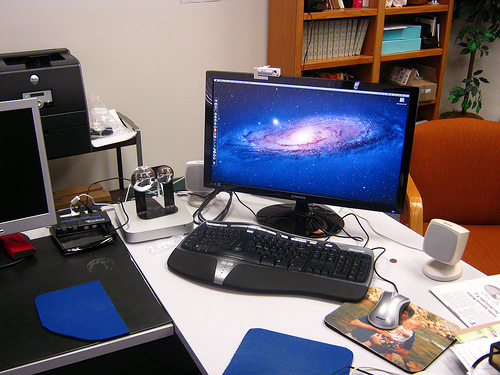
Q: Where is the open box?
A: In the bookcase.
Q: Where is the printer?
A: On the stand near the desk.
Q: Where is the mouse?
A: On the mouse pad with a picture on it.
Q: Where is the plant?
A: The corner.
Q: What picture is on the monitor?
A: A space galaxy.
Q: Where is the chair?
A: Near the bookcase.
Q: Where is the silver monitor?
A: Black desk.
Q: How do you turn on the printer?
A: The silver button.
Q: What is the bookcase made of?
A: Wood.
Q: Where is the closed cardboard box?
A: Printer stand.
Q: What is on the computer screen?
A: Picture of solar system.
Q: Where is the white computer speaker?
A: On the desk.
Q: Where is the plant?
A: In the corner.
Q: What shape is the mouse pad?
A: Square.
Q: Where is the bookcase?
A: Beside the tree.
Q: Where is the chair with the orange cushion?
A: Behind the desk.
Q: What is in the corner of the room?
A: A tree.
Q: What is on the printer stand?
A: A printer.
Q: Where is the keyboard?
A: On top of the desk.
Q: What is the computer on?
A: A white desk.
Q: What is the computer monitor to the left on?
A: A black desk.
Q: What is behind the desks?
A: An orange chair.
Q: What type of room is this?
A: Office.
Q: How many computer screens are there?
A: 2.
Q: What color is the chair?
A: Orange.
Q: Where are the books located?
A: Bookshelf.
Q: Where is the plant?
A: Corner.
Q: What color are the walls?
A: White.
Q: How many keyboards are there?
A: 1.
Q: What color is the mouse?
A: Silver.